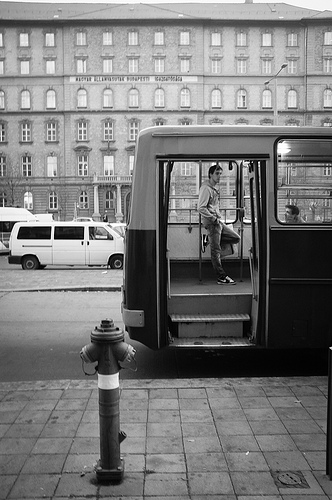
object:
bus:
[119, 117, 332, 355]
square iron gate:
[271, 468, 310, 489]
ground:
[4, 379, 327, 500]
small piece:
[245, 450, 250, 457]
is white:
[97, 371, 121, 391]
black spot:
[53, 415, 60, 425]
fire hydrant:
[78, 317, 135, 488]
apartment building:
[0, 0, 331, 241]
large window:
[78, 155, 88, 176]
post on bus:
[197, 163, 205, 285]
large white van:
[7, 222, 126, 271]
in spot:
[2, 262, 127, 288]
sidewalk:
[3, 379, 332, 496]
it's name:
[75, 74, 183, 83]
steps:
[171, 312, 253, 337]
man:
[283, 202, 307, 227]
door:
[155, 155, 267, 353]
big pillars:
[91, 182, 102, 224]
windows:
[46, 89, 56, 110]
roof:
[2, 0, 331, 32]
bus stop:
[120, 128, 329, 376]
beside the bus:
[2, 352, 332, 406]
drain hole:
[279, 470, 301, 485]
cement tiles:
[183, 458, 227, 499]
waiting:
[124, 117, 330, 380]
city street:
[0, 253, 174, 378]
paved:
[4, 291, 332, 382]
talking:
[197, 165, 306, 285]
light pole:
[265, 67, 282, 85]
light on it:
[279, 63, 289, 71]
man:
[195, 163, 240, 285]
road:
[0, 264, 126, 384]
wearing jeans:
[207, 225, 240, 278]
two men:
[199, 166, 308, 284]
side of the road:
[2, 263, 119, 285]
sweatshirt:
[198, 182, 220, 227]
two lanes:
[1, 230, 332, 391]